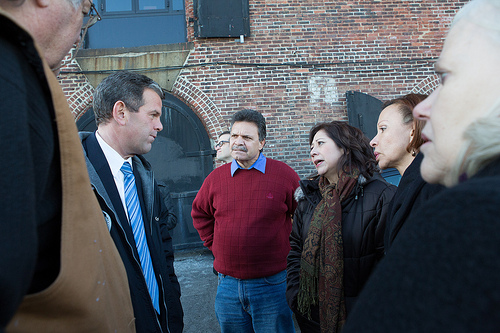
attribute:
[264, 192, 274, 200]
logo — maroon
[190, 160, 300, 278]
sweater — red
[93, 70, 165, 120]
hair — short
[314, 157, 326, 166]
mouth — open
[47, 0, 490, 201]
wall — brick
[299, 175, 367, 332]
scarf — long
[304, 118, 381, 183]
hair — long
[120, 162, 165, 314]
necktie — blue, striped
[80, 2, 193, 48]
window — closed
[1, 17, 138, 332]
vest — brown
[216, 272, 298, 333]
jeans — blue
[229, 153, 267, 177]
collar — blue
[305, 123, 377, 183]
woman's head — tilted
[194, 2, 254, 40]
shutter — black